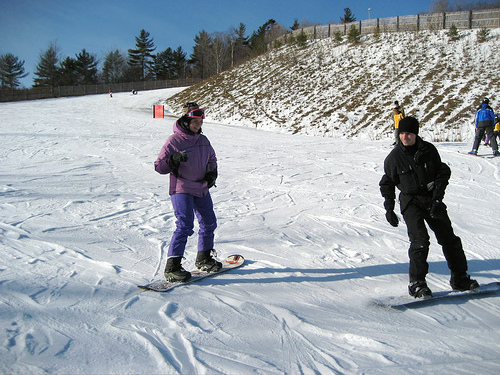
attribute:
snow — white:
[62, 145, 491, 371]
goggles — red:
[184, 104, 220, 129]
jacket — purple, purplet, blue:
[160, 116, 236, 200]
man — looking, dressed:
[373, 94, 481, 285]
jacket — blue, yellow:
[470, 96, 500, 136]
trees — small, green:
[264, 16, 364, 52]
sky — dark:
[54, 17, 236, 53]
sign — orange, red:
[149, 94, 174, 121]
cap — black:
[383, 112, 436, 154]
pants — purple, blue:
[173, 190, 235, 277]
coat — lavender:
[168, 131, 229, 190]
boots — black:
[395, 227, 481, 296]